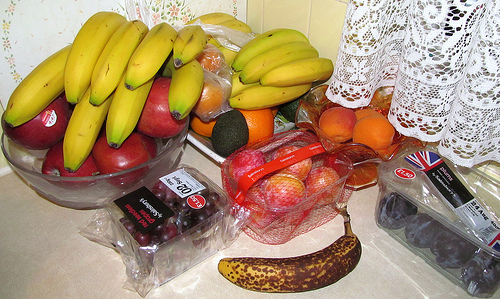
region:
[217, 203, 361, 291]
Brown spotted yellow banana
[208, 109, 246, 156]
Green avocado next to orange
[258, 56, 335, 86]
Banana next to banana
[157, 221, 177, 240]
Grape inside plastic box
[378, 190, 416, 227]
Plum next to plum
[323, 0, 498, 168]
White curtain above peach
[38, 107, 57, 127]
Sticker on large apple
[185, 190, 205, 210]
Red price sticker on plastic box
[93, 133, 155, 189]
Apple below large banana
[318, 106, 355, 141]
Peach next to peach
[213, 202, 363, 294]
Banana on a counter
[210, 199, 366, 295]
Banana is on a counter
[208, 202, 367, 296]
Banana with brown spots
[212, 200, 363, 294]
Banana has brown spots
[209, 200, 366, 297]
Browned banana on a counter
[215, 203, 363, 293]
Browned banana is on a counter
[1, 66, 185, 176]
Apples in a bowl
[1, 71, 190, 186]
Apples are in a bowl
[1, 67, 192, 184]
Red apples in a bowl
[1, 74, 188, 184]
Red apples are in a bowl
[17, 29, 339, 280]
Bananas and apples in the bowl.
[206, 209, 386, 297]
Banana on the table.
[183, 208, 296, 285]
Brown parts of the banana.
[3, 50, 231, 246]
Red apples in the bowl.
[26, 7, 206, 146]
Yellow bananas in the bowl.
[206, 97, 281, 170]
Avocado in the dish.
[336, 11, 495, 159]
Curtain on the window.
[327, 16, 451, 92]
White lace curtain.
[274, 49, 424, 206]
Peaches in the bowl.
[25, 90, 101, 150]
Stickers on the apple.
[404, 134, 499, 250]
Union Jack on packaging sticker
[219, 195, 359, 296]
overripe banana next to grapes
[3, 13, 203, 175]
bananas on top of red apples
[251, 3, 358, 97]
beige tiles behind bananas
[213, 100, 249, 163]
one avocado in front of oranges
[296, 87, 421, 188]
apricots in orange bowl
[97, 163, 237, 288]
package of purple grapes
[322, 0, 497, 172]
white lace curtains in upper right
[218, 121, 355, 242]
nectarines in netted packaging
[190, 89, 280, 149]
oranges behind avocado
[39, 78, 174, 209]
apples in the bowl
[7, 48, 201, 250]
apples in the bowl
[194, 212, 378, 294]
banana's skin is brown